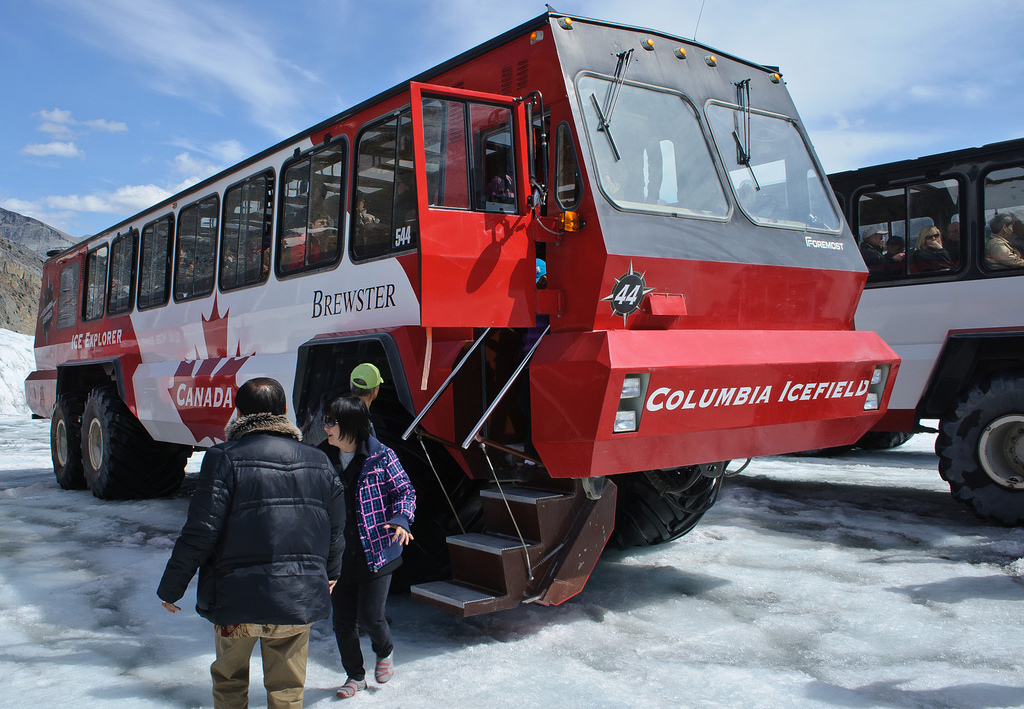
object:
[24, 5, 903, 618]
vehicle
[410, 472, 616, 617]
stairs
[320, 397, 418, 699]
girl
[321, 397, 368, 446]
hair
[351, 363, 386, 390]
baseball cap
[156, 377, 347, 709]
men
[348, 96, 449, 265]
window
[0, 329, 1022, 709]
ground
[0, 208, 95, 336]
mountain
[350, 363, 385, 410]
man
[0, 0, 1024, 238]
sky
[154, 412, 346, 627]
coat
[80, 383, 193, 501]
tires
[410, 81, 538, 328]
door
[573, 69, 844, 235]
windshield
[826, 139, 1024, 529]
truck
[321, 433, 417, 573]
jacket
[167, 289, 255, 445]
maple leaf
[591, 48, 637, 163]
wipers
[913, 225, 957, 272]
woman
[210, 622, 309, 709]
pants